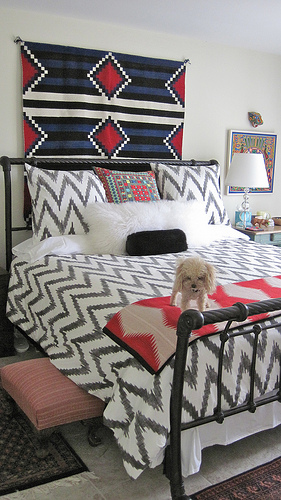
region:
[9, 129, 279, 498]
dog standing at end of bed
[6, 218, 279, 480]
grey and white comforter on bed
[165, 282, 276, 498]
black frame on bedq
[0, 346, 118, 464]
brown stool next to bed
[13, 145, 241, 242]
grey and white pillow on bed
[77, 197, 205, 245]
long white pillow on bed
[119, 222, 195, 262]
black pillow on bed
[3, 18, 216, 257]
multicolored tapestry on wall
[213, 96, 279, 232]
multicolored picture on wall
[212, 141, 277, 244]
lamp on sidetable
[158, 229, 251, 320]
Dog standing on the bed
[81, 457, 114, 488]
Floor is made of tile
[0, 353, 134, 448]
Foot stool beside the bed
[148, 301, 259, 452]
Bed frame is made of metal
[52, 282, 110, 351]
Chevron pattern on the bed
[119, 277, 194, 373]
Small blanket folded on bed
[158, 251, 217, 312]
Dog is looking at the bed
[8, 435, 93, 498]
Small rug under the footstool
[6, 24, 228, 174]
Cloth hanging on the wall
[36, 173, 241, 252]
Pillows on the bed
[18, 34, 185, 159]
woven wall hanging of stripes and diamonds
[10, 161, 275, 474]
gray and white zigzag pattern over pillows and bed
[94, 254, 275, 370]
small white dog standing on red and white fabric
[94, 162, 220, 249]
black tubular pillow, fluffy white pillow and multi-color pillow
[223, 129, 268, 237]
lamp with white shade on top of end table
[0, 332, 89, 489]
pink and white bench over dark patterned rug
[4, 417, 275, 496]
gray and tan marbled tiles on floor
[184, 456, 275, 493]
dark patterned rug on floor by bed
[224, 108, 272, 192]
animal head over framed artwork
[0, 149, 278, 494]
black metal headboard and footboards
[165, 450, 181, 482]
edge of a bed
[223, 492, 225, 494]
edge of a mat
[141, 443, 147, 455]
part of a blanket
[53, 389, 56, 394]
part of a chair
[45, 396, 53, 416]
edge of a chair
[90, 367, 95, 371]
white fabric on cover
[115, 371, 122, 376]
white fabric on cover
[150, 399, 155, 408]
white fabric on cover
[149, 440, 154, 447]
white fabric on cover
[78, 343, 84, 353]
white fabric on cover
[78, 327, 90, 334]
white fabric on cover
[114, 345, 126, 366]
white fabric on cover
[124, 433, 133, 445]
white fabric on cover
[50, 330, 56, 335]
white fabric on cover